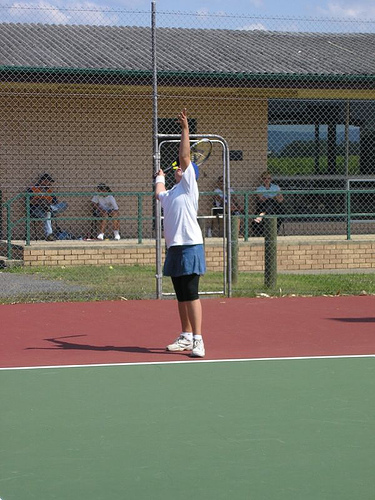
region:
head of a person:
[171, 147, 207, 181]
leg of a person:
[186, 286, 218, 335]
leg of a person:
[173, 288, 196, 331]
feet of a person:
[169, 338, 191, 348]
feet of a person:
[186, 339, 215, 352]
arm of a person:
[150, 173, 166, 205]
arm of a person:
[168, 121, 207, 178]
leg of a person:
[96, 216, 113, 239]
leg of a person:
[252, 200, 277, 231]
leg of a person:
[228, 209, 252, 240]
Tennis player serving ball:
[142, 107, 220, 360]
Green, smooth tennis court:
[1, 356, 373, 496]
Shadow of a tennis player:
[23, 331, 167, 355]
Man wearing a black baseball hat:
[23, 172, 73, 242]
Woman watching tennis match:
[249, 167, 283, 224]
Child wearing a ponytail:
[88, 180, 124, 240]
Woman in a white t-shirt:
[145, 105, 216, 360]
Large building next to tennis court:
[199, 37, 372, 227]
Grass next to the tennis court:
[280, 266, 373, 294]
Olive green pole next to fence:
[260, 212, 279, 292]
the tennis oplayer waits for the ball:
[143, 91, 221, 363]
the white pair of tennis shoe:
[166, 325, 207, 360]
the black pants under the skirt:
[166, 272, 204, 304]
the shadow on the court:
[19, 331, 166, 363]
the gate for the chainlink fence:
[206, 137, 235, 297]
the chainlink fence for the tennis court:
[255, 13, 374, 298]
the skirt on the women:
[156, 242, 206, 281]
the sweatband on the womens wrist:
[153, 173, 169, 192]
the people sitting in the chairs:
[27, 169, 125, 246]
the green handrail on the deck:
[2, 192, 143, 239]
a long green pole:
[238, 185, 374, 197]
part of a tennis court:
[0, 298, 369, 494]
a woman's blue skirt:
[159, 242, 208, 276]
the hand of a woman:
[175, 105, 194, 130]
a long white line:
[203, 352, 373, 365]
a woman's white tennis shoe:
[189, 338, 209, 356]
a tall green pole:
[262, 213, 282, 286]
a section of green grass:
[278, 272, 373, 292]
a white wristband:
[155, 170, 167, 184]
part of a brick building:
[2, 87, 124, 171]